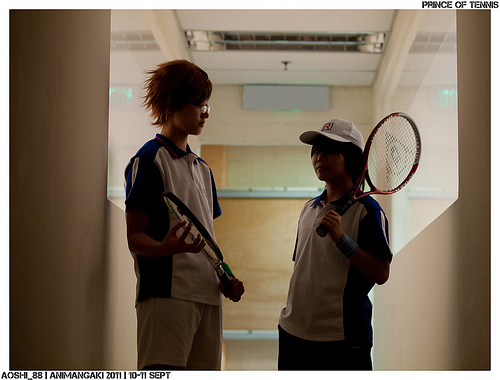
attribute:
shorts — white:
[134, 297, 222, 370]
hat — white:
[299, 118, 364, 155]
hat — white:
[288, 107, 373, 153]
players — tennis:
[106, 53, 436, 365]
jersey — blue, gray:
[124, 133, 221, 297]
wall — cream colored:
[417, 212, 491, 304]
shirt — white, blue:
[277, 188, 394, 343]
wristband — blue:
[335, 234, 366, 258]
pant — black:
[273, 337, 379, 371]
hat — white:
[297, 118, 364, 150]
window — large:
[105, 4, 187, 226]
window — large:
[378, 11, 468, 269]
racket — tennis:
[338, 109, 489, 214]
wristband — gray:
[334, 232, 356, 259]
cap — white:
[296, 117, 368, 156]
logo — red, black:
[320, 120, 336, 131]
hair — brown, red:
[142, 57, 212, 127]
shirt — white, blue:
[120, 130, 224, 306]